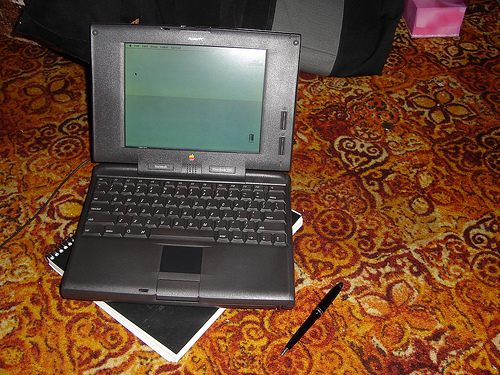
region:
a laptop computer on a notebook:
[47, 15, 344, 351]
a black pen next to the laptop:
[263, 257, 357, 367]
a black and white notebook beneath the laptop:
[42, 205, 311, 357]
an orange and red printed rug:
[333, 116, 486, 261]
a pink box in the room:
[398, 0, 478, 42]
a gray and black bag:
[19, 3, 398, 83]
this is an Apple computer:
[114, 35, 304, 172]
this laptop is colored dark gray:
[60, 17, 336, 319]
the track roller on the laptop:
[143, 240, 216, 275]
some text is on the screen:
[118, 36, 268, 153]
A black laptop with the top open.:
[57, 23, 298, 304]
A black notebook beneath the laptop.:
[46, 63, 301, 359]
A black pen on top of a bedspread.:
[274, 278, 345, 355]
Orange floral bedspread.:
[0, 65, 497, 373]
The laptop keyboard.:
[80, 171, 286, 248]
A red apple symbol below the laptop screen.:
[181, 151, 196, 164]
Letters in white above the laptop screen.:
[185, 34, 206, 42]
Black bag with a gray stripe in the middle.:
[206, 0, 399, 73]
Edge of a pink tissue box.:
[405, 3, 467, 40]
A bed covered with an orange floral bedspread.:
[1, 0, 499, 374]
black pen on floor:
[277, 278, 350, 356]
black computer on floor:
[57, 20, 296, 311]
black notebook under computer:
[43, 201, 310, 361]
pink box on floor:
[397, 0, 469, 46]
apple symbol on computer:
[185, 152, 197, 162]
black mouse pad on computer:
[155, 244, 208, 273]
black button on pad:
[152, 275, 204, 302]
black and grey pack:
[201, 0, 417, 80]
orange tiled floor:
[5, 2, 495, 372]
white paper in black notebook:
[37, 215, 304, 359]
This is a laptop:
[68, 25, 318, 317]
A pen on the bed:
[256, 265, 397, 373]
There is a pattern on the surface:
[336, 158, 490, 268]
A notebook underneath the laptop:
[24, 158, 347, 348]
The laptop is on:
[103, 22, 290, 171]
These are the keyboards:
[82, 161, 304, 263]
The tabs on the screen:
[110, 33, 195, 55]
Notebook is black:
[28, 168, 335, 358]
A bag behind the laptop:
[18, 3, 427, 100]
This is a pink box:
[406, 3, 473, 53]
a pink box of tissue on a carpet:
[403, 2, 466, 39]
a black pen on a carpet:
[283, 279, 343, 357]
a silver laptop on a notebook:
[58, 25, 300, 305]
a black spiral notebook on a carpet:
[46, 209, 304, 361]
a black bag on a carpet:
[13, 3, 405, 75]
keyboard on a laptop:
[83, 175, 286, 248]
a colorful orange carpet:
[1, 2, 495, 372]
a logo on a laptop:
[188, 150, 196, 162]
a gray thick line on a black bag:
[270, 0, 346, 73]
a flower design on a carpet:
[413, 89, 475, 124]